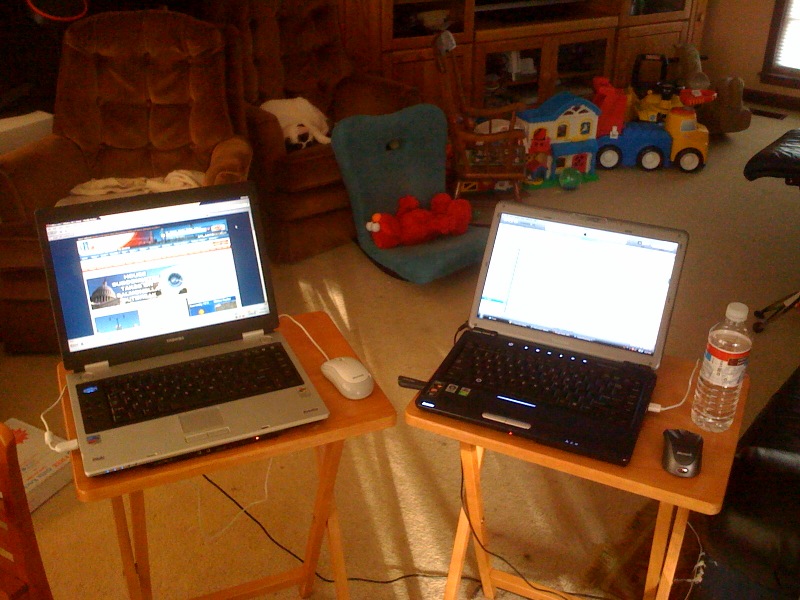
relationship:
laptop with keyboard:
[416, 201, 688, 466] [413, 328, 660, 467]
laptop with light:
[416, 201, 688, 466] [496, 389, 538, 409]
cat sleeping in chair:
[260, 93, 338, 152] [218, 2, 458, 259]